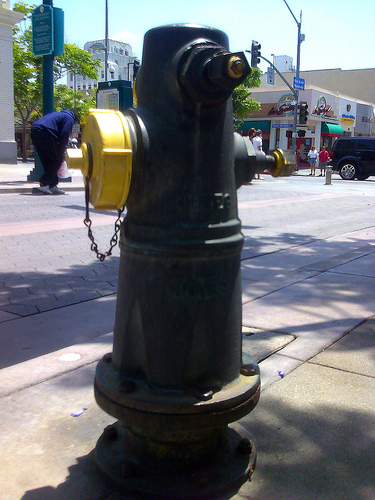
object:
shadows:
[6, 228, 349, 351]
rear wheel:
[339, 159, 358, 181]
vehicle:
[330, 134, 375, 180]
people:
[307, 146, 330, 177]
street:
[0, 189, 117, 331]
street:
[248, 181, 369, 258]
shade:
[22, 388, 373, 498]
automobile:
[329, 135, 374, 182]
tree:
[57, 49, 96, 111]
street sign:
[32, 5, 53, 58]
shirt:
[30, 110, 75, 155]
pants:
[31, 125, 64, 188]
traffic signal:
[296, 100, 308, 124]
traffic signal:
[133, 58, 140, 81]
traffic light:
[249, 40, 261, 68]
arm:
[244, 39, 298, 98]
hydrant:
[62, 22, 297, 498]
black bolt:
[194, 386, 213, 400]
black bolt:
[240, 364, 257, 376]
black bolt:
[118, 380, 137, 393]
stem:
[64, 108, 133, 212]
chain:
[84, 142, 126, 262]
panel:
[234, 317, 284, 357]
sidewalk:
[63, 253, 372, 445]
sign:
[32, 4, 54, 57]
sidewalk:
[0, 152, 100, 185]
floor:
[190, 91, 232, 111]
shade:
[285, 409, 369, 492]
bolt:
[94, 417, 258, 497]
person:
[319, 146, 330, 177]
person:
[308, 145, 319, 176]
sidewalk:
[293, 164, 336, 176]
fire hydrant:
[65, 23, 297, 495]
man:
[31, 109, 78, 194]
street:
[297, 162, 374, 213]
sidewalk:
[9, 247, 373, 497]